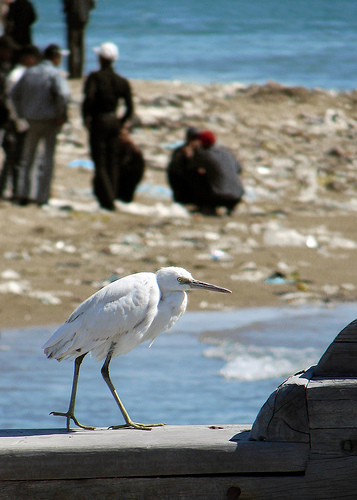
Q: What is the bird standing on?
A: A fence.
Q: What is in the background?
A: A beach.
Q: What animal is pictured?
A: Bird.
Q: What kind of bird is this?
A: Seagull.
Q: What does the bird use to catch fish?
A: Beak.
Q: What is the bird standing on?
A: Wooden perch.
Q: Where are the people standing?
A: Beach.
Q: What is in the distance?
A: The ocean.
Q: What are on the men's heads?
A: Hats.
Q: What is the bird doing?
A: Standing.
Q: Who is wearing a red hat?
A: The guy kneeling down.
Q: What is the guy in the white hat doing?
A: Standing around.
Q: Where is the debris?
A: All over the sand.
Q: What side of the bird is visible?
A: The right side.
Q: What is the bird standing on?
A: A fence.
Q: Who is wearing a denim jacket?
A: The guy to the left of the guy in the white hat.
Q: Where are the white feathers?
A: On the bird.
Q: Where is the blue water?
A: On either side of the sand.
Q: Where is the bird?
A: On a wooden ledge.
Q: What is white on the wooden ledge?
A: A bird.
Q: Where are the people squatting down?
A: On the river bank.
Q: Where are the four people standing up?
A: On a river bank.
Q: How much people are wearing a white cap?
A: One.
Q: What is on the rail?
A: Bird.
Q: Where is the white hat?
A: On his head.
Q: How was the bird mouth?
A: Close.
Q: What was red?
A: Hat.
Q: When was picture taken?
A: Daytime.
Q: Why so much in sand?
A: Trash.